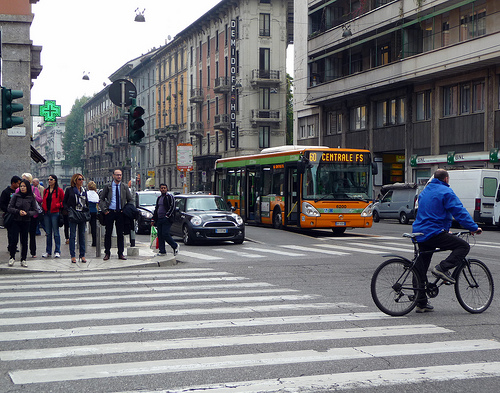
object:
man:
[410, 166, 482, 313]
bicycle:
[370, 228, 493, 317]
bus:
[213, 143, 373, 233]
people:
[2, 167, 174, 268]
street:
[0, 221, 498, 392]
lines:
[1, 234, 498, 392]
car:
[167, 192, 246, 246]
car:
[131, 190, 159, 233]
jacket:
[412, 179, 479, 244]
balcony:
[306, 1, 496, 109]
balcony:
[250, 49, 281, 89]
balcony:
[251, 88, 282, 125]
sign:
[31, 99, 63, 123]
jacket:
[40, 186, 65, 215]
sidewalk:
[2, 222, 179, 274]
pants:
[415, 231, 469, 304]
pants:
[155, 221, 176, 250]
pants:
[105, 209, 126, 253]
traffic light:
[125, 105, 147, 147]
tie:
[114, 184, 121, 210]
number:
[307, 149, 319, 164]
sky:
[29, 1, 216, 133]